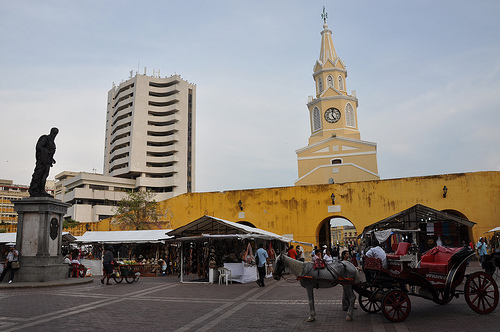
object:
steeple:
[320, 5, 330, 30]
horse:
[271, 254, 362, 322]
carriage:
[357, 237, 499, 322]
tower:
[305, 5, 362, 143]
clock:
[322, 107, 342, 123]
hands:
[329, 108, 338, 121]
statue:
[27, 125, 59, 196]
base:
[11, 196, 70, 282]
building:
[54, 63, 198, 222]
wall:
[61, 172, 500, 266]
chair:
[221, 261, 261, 283]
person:
[254, 241, 270, 287]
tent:
[75, 214, 314, 248]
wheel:
[381, 288, 412, 322]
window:
[148, 79, 181, 87]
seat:
[418, 243, 457, 273]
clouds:
[360, 76, 500, 143]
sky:
[1, 0, 500, 191]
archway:
[310, 215, 362, 256]